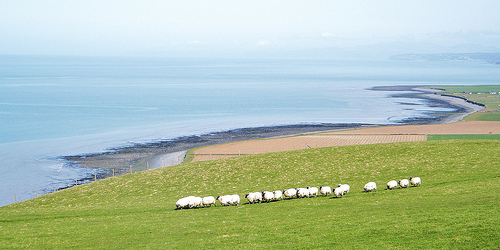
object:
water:
[0, 50, 499, 204]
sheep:
[243, 191, 263, 204]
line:
[172, 183, 350, 210]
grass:
[0, 84, 500, 250]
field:
[0, 138, 500, 250]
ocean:
[0, 55, 497, 207]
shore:
[190, 123, 361, 135]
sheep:
[364, 181, 378, 191]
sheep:
[385, 179, 402, 190]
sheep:
[398, 178, 411, 189]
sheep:
[409, 176, 422, 186]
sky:
[0, 0, 500, 60]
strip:
[185, 123, 500, 163]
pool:
[465, 92, 500, 95]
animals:
[244, 191, 264, 203]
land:
[0, 139, 500, 250]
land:
[192, 134, 426, 154]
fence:
[11, 158, 178, 204]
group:
[172, 183, 350, 209]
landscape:
[0, 0, 499, 250]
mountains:
[393, 53, 500, 65]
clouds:
[0, 0, 500, 53]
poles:
[14, 193, 17, 206]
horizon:
[0, 58, 500, 62]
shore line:
[49, 85, 485, 193]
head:
[386, 185, 394, 189]